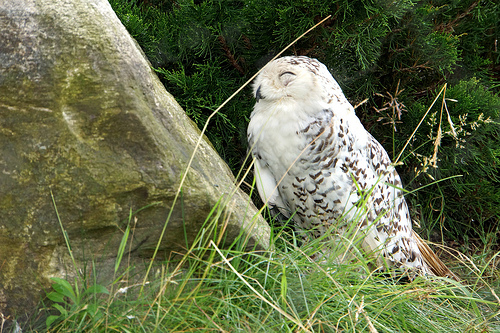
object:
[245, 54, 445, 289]
owl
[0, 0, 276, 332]
rock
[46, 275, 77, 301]
leaf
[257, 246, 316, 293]
grass